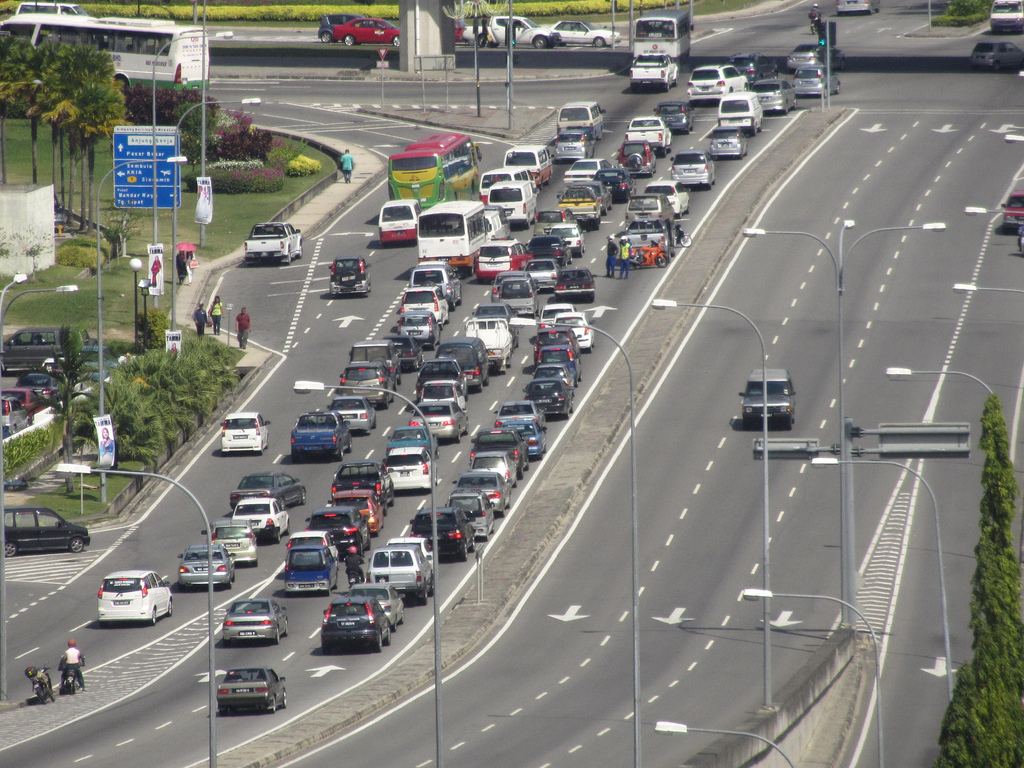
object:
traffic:
[0, 0, 833, 717]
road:
[0, 0, 1022, 766]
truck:
[291, 411, 352, 461]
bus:
[630, 11, 691, 67]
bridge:
[399, 1, 456, 72]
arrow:
[307, 103, 556, 111]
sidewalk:
[169, 160, 435, 358]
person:
[233, 308, 250, 351]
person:
[176, 250, 187, 285]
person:
[184, 250, 193, 284]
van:
[0, 510, 93, 557]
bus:
[388, 132, 486, 211]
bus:
[0, 13, 214, 91]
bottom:
[128, 78, 211, 92]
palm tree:
[41, 38, 124, 231]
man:
[611, 232, 635, 278]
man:
[603, 237, 619, 280]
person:
[192, 302, 208, 336]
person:
[208, 297, 225, 337]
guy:
[340, 149, 356, 184]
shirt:
[340, 154, 353, 171]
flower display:
[121, 80, 323, 196]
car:
[216, 665, 288, 713]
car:
[176, 544, 236, 588]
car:
[202, 520, 259, 566]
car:
[228, 496, 291, 543]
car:
[230, 470, 307, 513]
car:
[378, 445, 435, 489]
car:
[222, 599, 290, 645]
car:
[98, 570, 174, 626]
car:
[737, 367, 798, 430]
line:
[651, 560, 659, 572]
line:
[665, 534, 674, 546]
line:
[679, 508, 687, 520]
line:
[706, 460, 715, 469]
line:
[638, 586, 644, 595]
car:
[221, 411, 271, 455]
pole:
[646, 298, 777, 710]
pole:
[509, 315, 640, 766]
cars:
[718, 90, 764, 136]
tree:
[931, 389, 1021, 766]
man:
[57, 639, 87, 696]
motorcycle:
[61, 670, 85, 695]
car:
[321, 595, 390, 654]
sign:
[112, 126, 184, 210]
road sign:
[751, 422, 972, 461]